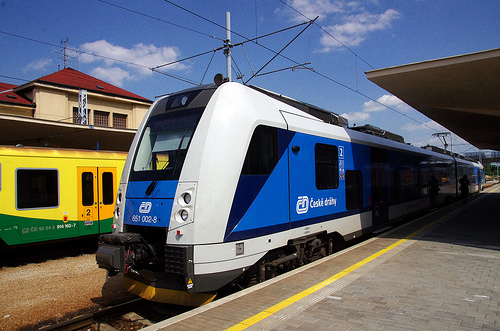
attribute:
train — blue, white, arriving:
[92, 71, 482, 297]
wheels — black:
[0, 238, 22, 268]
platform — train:
[203, 190, 484, 316]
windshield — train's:
[130, 105, 202, 171]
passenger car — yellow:
[3, 146, 128, 251]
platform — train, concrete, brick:
[132, 183, 499, 330]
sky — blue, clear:
[1, 4, 498, 153]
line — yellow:
[222, 185, 499, 330]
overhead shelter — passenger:
[365, 49, 499, 248]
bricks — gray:
[271, 248, 499, 330]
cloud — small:
[319, 7, 398, 49]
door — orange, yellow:
[78, 167, 99, 235]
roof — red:
[14, 65, 152, 104]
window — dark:
[314, 143, 339, 189]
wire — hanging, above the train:
[159, 0, 438, 133]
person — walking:
[455, 171, 472, 208]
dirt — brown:
[1, 252, 105, 328]